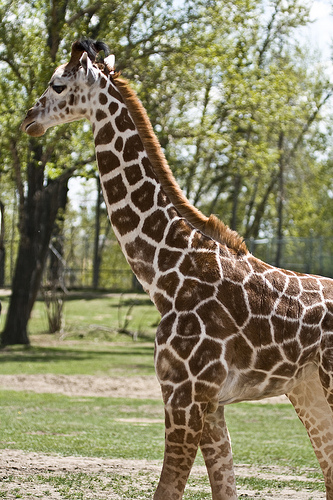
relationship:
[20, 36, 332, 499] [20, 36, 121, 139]
giraffe has head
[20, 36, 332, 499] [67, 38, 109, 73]
giraffe has horns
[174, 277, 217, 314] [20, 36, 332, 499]
spot on side of giraffe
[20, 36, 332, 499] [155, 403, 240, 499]
giraffe has legs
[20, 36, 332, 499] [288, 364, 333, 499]
giraffe has hind legs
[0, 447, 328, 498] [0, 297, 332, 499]
road in ground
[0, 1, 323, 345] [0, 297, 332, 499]
tree in ground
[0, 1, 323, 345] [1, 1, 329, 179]
tree has leaves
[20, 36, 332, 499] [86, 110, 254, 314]
giraffe has neck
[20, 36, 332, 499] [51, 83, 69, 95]
giraffe has left eye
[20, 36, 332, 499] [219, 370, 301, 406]
giraffe has stomach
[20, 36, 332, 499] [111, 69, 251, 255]
giraffe has mane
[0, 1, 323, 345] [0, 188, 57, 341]
tree has tree trunk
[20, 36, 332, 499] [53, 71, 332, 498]
giraffe has spots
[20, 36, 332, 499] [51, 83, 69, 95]
giraffe has eye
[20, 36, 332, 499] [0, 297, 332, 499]
giraffe in ground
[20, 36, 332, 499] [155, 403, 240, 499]
giraffe has front legs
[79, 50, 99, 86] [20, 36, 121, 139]
ear on head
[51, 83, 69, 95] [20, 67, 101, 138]
eye on face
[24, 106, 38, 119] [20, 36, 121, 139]
snout on head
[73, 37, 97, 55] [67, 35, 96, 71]
fur on horn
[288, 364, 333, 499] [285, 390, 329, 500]
hind legs has edge